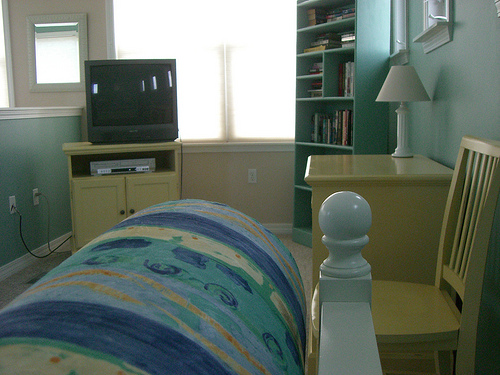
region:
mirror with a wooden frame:
[24, 11, 86, 93]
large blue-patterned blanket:
[3, 196, 302, 373]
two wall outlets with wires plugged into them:
[7, 185, 76, 258]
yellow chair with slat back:
[310, 135, 499, 371]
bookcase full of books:
[293, 0, 394, 251]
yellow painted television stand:
[61, 141, 181, 255]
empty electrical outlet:
[246, 166, 259, 186]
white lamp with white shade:
[373, 63, 433, 158]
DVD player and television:
[83, 56, 179, 176]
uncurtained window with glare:
[113, 1, 296, 139]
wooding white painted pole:
[304, 172, 400, 369]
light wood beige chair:
[361, 133, 496, 350]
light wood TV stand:
[56, 134, 217, 247]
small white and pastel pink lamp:
[372, 71, 450, 163]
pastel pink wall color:
[194, 150, 292, 222]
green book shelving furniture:
[289, 74, 391, 253]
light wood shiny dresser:
[298, 149, 470, 290]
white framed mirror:
[15, 2, 95, 104]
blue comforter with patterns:
[39, 198, 336, 373]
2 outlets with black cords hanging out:
[4, 179, 78, 257]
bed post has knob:
[308, 186, 393, 295]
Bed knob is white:
[318, 180, 395, 250]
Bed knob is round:
[308, 182, 400, 249]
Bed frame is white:
[304, 188, 404, 373]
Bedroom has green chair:
[306, 135, 496, 370]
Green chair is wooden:
[311, 124, 496, 373]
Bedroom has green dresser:
[291, 137, 466, 295]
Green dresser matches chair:
[293, 141, 497, 311]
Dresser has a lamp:
[363, 56, 453, 176]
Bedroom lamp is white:
[375, 61, 440, 169]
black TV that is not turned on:
[82, 62, 180, 144]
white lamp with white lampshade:
[373, 67, 430, 159]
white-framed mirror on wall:
[19, 13, 94, 94]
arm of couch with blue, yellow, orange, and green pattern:
[0, 196, 307, 373]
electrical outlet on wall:
[243, 166, 258, 186]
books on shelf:
[297, 24, 359, 144]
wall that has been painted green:
[11, 137, 61, 167]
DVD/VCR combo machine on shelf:
[87, 160, 164, 173]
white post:
[319, 189, 370, 278]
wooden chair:
[347, 128, 497, 373]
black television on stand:
[82, 56, 179, 143]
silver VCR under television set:
[87, 156, 158, 177]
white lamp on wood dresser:
[378, 64, 432, 156]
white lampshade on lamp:
[372, 63, 433, 103]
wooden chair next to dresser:
[306, 136, 498, 373]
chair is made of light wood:
[311, 133, 499, 373]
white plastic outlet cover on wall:
[30, 187, 42, 205]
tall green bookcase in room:
[293, 0, 393, 246]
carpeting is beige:
[271, 231, 319, 343]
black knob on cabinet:
[119, 208, 126, 215]